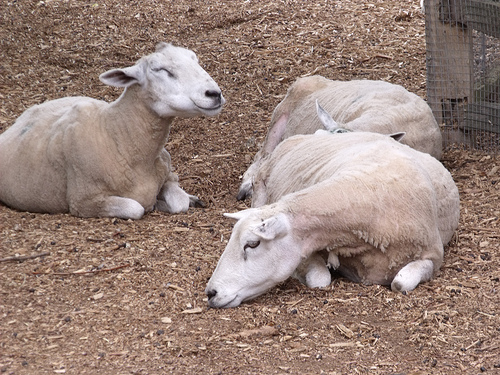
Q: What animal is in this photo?
A: Goats.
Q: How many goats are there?
A: Three.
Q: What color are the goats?
A: White.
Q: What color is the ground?
A: Brown.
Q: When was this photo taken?
A: Daytime.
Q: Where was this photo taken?
A: At a farm.